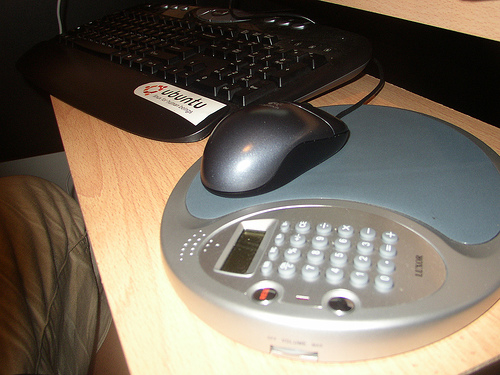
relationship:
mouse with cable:
[200, 98, 349, 200] [333, 61, 386, 118]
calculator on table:
[182, 210, 445, 323] [37, 8, 481, 361]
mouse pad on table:
[184, 104, 499, 246] [37, 8, 481, 361]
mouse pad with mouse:
[207, 100, 484, 228] [209, 95, 349, 180]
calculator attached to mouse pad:
[200, 204, 446, 313] [184, 104, 499, 246]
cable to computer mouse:
[326, 54, 399, 124] [197, 95, 353, 187]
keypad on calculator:
[277, 217, 405, 291] [205, 210, 436, 316]